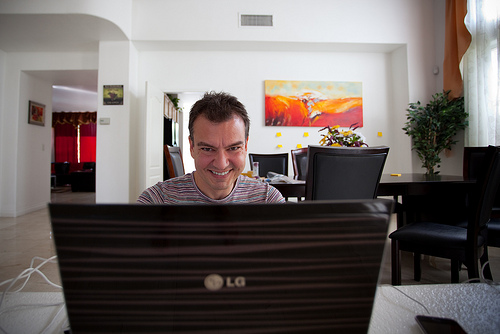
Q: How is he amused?
A: Watching a LG device.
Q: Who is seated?
A: The amused man.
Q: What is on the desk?
A: A phone.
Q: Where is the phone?
A: Next to the LG device.